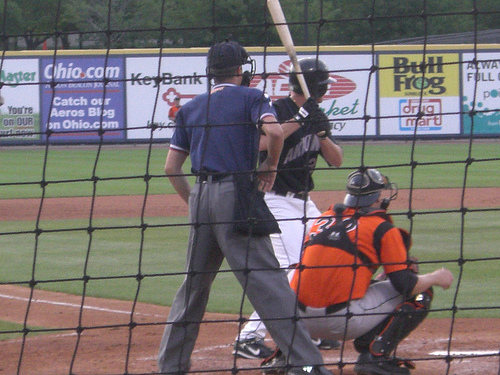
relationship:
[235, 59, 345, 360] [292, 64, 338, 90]
player wearing helmet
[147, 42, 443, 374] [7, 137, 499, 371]
men playing baseball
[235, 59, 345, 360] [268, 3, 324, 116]
player ready to swing bat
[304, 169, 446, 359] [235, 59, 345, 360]
catcher by player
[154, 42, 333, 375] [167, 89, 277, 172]
men wears a blue shirt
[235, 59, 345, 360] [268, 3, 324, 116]
player holding bat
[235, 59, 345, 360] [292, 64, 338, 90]
player wearing a helmet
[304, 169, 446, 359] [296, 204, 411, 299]
catcher wearing a jersey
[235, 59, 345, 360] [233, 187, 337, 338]
player wearing pants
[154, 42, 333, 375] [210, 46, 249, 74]
men wearing a hat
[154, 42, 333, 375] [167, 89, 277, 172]
men wearing a shirt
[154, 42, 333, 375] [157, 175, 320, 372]
men wearing gray pants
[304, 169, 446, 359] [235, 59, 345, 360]
catcher next to player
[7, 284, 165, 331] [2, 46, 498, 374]
line on field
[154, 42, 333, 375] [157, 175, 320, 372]
men wears pants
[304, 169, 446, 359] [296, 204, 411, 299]
catcher wearing jersey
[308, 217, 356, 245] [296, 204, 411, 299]
number on jersey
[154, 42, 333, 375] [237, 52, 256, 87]
men wearing a mask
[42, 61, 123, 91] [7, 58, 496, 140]
sponsor on wall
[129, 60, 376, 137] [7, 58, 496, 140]
poster on wall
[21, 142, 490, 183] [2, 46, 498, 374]
grass on field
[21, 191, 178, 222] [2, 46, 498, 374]
dirt on field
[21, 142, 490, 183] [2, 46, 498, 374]
grass in field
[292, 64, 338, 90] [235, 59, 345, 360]
helmet on player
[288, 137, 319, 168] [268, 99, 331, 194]
word on jersey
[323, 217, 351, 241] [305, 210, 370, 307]
strap on back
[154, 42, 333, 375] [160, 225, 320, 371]
men has legs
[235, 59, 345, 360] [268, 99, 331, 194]
player wearing a jersey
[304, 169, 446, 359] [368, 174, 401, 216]
catcher wearing mask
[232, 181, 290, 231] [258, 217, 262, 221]
bag for baseballs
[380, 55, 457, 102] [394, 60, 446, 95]
advertising for bull frog